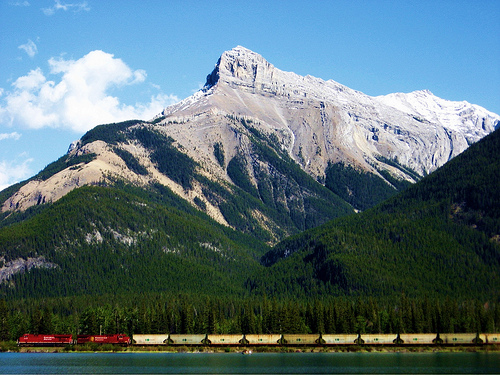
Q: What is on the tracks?
A: A train.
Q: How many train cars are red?
A: Two.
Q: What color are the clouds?
A: White.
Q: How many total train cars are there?
A: Twelve.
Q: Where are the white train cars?
A: Behind the red ones.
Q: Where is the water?
A: In front of the train.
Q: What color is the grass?
A: Green.